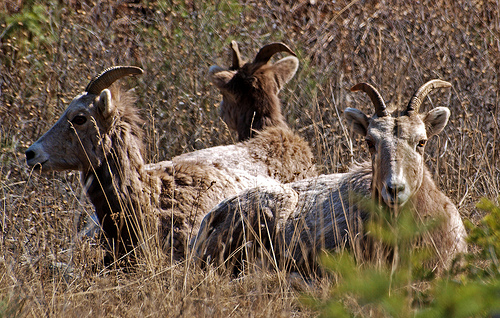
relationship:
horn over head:
[252, 41, 298, 67] [12, 62, 146, 171]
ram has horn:
[186, 80, 470, 283] [347, 83, 387, 117]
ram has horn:
[186, 80, 470, 283] [402, 76, 452, 111]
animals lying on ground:
[23, 64, 179, 280] [10, 181, 489, 312]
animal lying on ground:
[135, 39, 321, 269] [10, 181, 489, 312]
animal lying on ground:
[197, 77, 467, 285] [10, 181, 489, 312]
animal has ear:
[197, 77, 467, 285] [425, 107, 445, 134]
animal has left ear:
[197, 77, 467, 285] [414, 93, 467, 151]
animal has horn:
[197, 77, 467, 285] [349, 79, 388, 113]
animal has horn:
[197, 77, 467, 285] [406, 77, 452, 113]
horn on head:
[82, 64, 145, 90] [23, 85, 116, 173]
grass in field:
[7, 15, 467, 289] [23, 10, 493, 307]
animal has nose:
[197, 77, 467, 285] [386, 181, 405, 196]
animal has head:
[135, 39, 321, 269] [341, 76, 458, 211]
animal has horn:
[197, 77, 467, 285] [409, 73, 451, 116]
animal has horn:
[197, 77, 467, 285] [348, 77, 390, 117]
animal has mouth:
[197, 77, 467, 285] [385, 197, 406, 207]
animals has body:
[23, 64, 179, 280] [140, 126, 316, 268]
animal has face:
[197, 77, 467, 285] [365, 111, 428, 210]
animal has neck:
[135, 39, 321, 269] [234, 103, 289, 132]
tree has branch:
[281, 211, 498, 312] [324, 233, 486, 315]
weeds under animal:
[57, 196, 311, 316] [195, 76, 466, 276]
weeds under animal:
[57, 196, 311, 316] [211, 41, 302, 146]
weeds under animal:
[57, 196, 311, 316] [25, 63, 315, 280]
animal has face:
[195, 76, 466, 276] [365, 111, 428, 210]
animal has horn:
[195, 76, 466, 276] [406, 77, 452, 113]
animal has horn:
[195, 76, 466, 276] [347, 79, 388, 115]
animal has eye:
[195, 76, 466, 276] [415, 137, 427, 147]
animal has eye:
[195, 76, 466, 276] [365, 138, 375, 149]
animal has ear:
[188, 78, 470, 296] [422, 105, 452, 140]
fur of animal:
[120, 168, 188, 228] [118, 36, 315, 220]